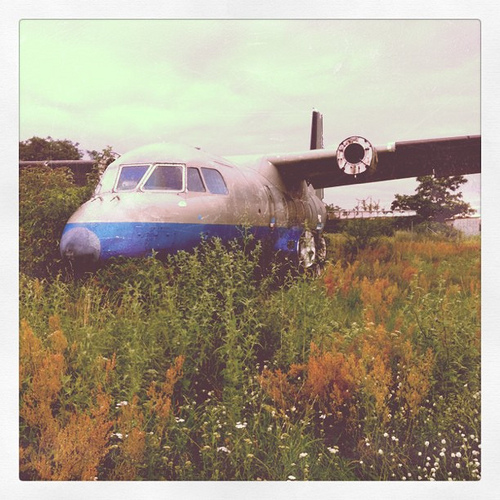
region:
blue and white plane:
[131, 130, 386, 299]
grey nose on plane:
[67, 230, 142, 276]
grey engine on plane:
[333, 135, 375, 171]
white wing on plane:
[295, 136, 486, 167]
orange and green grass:
[238, 275, 425, 473]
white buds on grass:
[154, 354, 488, 486]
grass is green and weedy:
[27, 270, 297, 461]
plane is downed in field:
[67, 116, 429, 281]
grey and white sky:
[152, 15, 267, 107]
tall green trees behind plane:
[15, 136, 91, 236]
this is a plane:
[40, 75, 425, 320]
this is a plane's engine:
[306, 116, 395, 211]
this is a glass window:
[105, 155, 145, 190]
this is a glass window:
[140, 160, 180, 190]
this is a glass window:
[180, 160, 200, 195]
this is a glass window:
[195, 150, 220, 195]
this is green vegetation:
[90, 265, 285, 350]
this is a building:
[352, 195, 480, 266]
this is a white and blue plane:
[30, 83, 495, 443]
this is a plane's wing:
[293, 119, 498, 309]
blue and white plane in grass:
[40, 112, 489, 307]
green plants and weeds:
[180, 290, 246, 348]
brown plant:
[43, 438, 88, 477]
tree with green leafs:
[406, 176, 465, 216]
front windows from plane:
[96, 154, 166, 196]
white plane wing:
[305, 127, 497, 203]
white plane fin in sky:
[287, 99, 337, 156]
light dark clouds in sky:
[147, 54, 215, 100]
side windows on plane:
[274, 197, 324, 221]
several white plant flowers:
[412, 434, 469, 473]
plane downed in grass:
[77, 119, 328, 306]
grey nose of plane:
[48, 218, 135, 297]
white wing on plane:
[273, 119, 493, 198]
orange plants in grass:
[299, 276, 452, 441]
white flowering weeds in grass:
[161, 370, 456, 473]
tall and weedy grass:
[124, 273, 313, 455]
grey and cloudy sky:
[108, 34, 309, 126]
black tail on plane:
[315, 117, 337, 214]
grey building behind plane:
[333, 202, 480, 251]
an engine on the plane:
[326, 134, 382, 174]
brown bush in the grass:
[261, 323, 424, 440]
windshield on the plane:
[97, 160, 185, 190]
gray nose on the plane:
[62, 229, 103, 264]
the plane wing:
[285, 130, 479, 183]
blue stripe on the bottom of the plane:
[67, 223, 308, 259]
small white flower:
[236, 422, 246, 427]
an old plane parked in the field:
[27, 108, 474, 276]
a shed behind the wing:
[444, 214, 479, 236]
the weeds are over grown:
[42, 249, 479, 476]